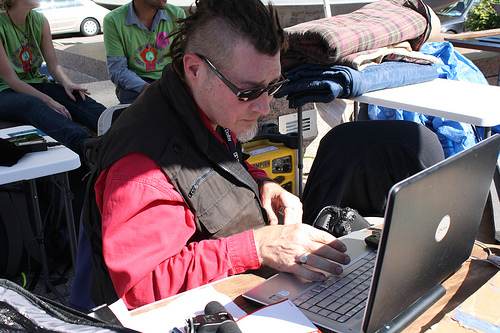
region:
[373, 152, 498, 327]
the laptop is black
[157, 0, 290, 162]
the person has a mohawk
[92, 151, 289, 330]
the shirt is red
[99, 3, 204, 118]
the shirt is green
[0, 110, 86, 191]
the table is white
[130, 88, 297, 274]
the vest is black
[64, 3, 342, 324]
the man is white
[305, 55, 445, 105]
the cloth is blue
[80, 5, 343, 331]
the man is sitting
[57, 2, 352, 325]
the man is typing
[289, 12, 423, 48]
Plaid blanket on the table.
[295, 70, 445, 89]
Dark blue blanket below the plaid blanket on the table.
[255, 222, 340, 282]
Right hand of the man at the laptop.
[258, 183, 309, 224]
Left hand of the man on the laptop.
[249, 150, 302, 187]
Yellow box under the table where the blankets are placed.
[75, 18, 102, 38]
Back tire of the white car parked in the background.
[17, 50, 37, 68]
Red ribbon on the green tank top worn by the woman.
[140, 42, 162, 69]
Red ribbon on the green t-shirt the man is wearing.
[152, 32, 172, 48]
Pink sticker on the green t-shirt worn by the man.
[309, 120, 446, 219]
Black jacket draped over the chair next to the man in the black vest.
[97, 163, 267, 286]
Red shirt sleeve of the man.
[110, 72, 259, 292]
Black vest worn by the man.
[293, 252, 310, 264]
Ring on the man's finger.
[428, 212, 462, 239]
Circle emblem on the man's laptop.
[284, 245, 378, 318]
Keyboard of the laptop.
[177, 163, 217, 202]
The zipper on the man's black vest.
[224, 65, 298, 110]
Black sunglasses the man is wearing.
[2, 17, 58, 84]
Green sleeveless tank to p the girl is wearing.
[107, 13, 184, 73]
Green shirt the man is wearing.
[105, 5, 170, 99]
Blue undershirt the man is wearing under his green t-shirt.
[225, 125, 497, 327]
A silver laptop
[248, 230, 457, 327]
The laptop's keyboard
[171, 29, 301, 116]
A pair of black sunglasses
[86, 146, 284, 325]
The sleeve of a red shirt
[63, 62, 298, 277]
A black vest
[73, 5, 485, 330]
A man using the laptop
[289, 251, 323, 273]
A ring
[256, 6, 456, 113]
A couple of folded blankets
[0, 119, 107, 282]
A white table with black legs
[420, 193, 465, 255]
The laptop's brand logo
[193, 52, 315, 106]
black glasses on face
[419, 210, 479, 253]
white logo on laptop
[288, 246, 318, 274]
large with ring on man's finger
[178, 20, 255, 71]
man's partial shaved head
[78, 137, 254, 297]
shiny pink shirt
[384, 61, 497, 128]
large smooth white surface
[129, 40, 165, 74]
pink and green symbol on shirt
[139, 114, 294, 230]
brown vest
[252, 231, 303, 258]
wrinkles on man's hand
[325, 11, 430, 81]
stack of clothes on table